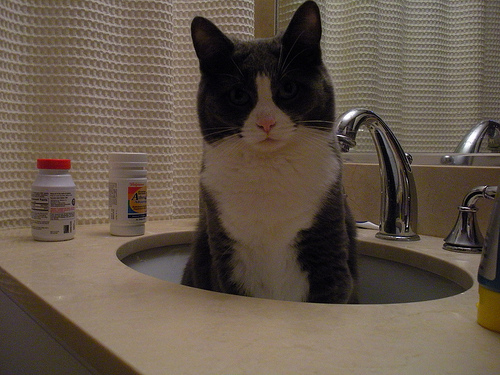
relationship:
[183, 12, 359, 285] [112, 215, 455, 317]
cat in sink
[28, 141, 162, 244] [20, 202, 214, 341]
bottles on counter